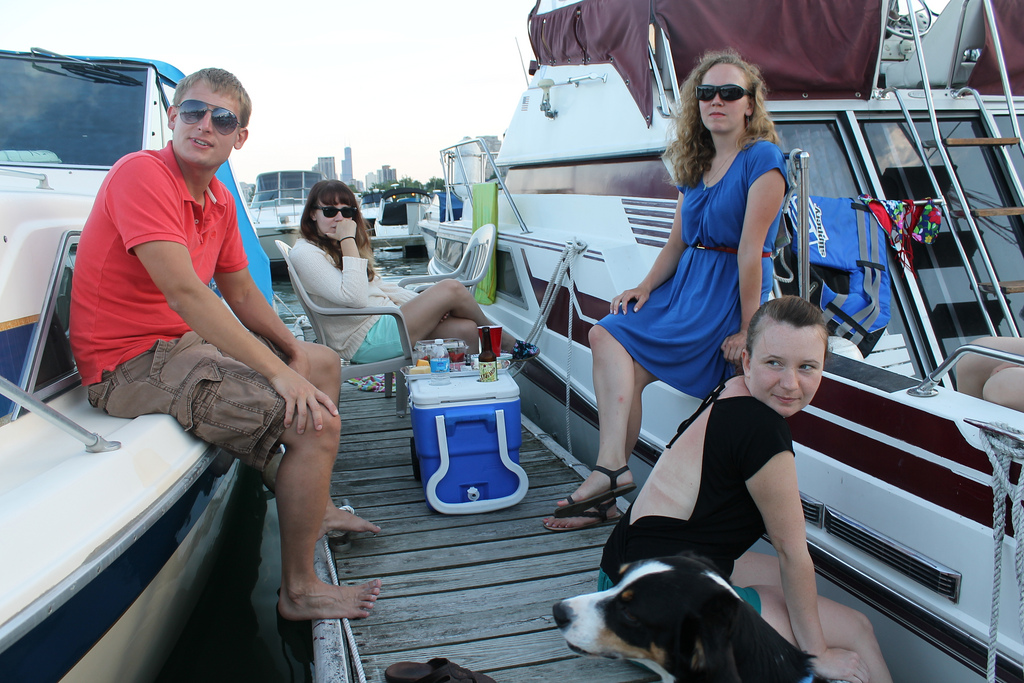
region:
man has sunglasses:
[155, 94, 248, 145]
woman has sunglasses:
[310, 200, 359, 224]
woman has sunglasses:
[692, 80, 754, 113]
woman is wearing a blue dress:
[597, 135, 788, 396]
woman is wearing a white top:
[294, 235, 387, 360]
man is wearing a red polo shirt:
[66, 134, 253, 375]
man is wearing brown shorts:
[63, 330, 289, 473]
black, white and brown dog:
[534, 554, 795, 679]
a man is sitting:
[71, 69, 385, 611]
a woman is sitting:
[596, 296, 895, 679]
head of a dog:
[554, 551, 793, 679]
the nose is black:
[552, 599, 572, 628]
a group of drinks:
[406, 322, 506, 386]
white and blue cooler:
[403, 368, 528, 514]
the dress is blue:
[601, 141, 786, 392]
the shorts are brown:
[90, 331, 284, 484]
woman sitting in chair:
[276, 179, 493, 407]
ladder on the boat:
[901, 94, 1022, 329]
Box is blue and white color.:
[405, 365, 536, 520]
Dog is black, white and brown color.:
[514, 554, 755, 681]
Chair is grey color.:
[266, 235, 419, 384]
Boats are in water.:
[0, 97, 314, 677]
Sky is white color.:
[265, 37, 465, 139]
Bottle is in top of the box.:
[411, 309, 513, 411]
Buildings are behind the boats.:
[305, 140, 410, 199]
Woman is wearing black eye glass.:
[632, 55, 787, 373]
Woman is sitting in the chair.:
[297, 172, 481, 454]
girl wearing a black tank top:
[592, 301, 890, 679]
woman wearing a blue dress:
[547, 54, 779, 535]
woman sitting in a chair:
[273, 173, 534, 363]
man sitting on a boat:
[2, 45, 383, 672]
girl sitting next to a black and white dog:
[547, 291, 901, 680]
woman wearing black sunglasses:
[659, 48, 778, 146]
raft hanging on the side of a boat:
[408, 135, 533, 333]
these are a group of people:
[119, 61, 945, 618]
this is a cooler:
[356, 317, 576, 542]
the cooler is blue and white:
[348, 368, 623, 653]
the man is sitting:
[62, 89, 376, 494]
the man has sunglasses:
[128, 83, 334, 150]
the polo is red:
[45, 142, 324, 395]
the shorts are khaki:
[61, 330, 347, 485]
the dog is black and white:
[529, 570, 805, 666]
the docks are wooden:
[368, 521, 569, 680]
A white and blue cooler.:
[398, 361, 535, 516]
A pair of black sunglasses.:
[697, 80, 751, 103]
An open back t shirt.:
[597, 383, 794, 580]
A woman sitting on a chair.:
[284, 178, 544, 360]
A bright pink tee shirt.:
[62, 143, 249, 387]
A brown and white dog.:
[548, 550, 839, 677]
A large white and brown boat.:
[382, 0, 1021, 677]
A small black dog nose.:
[546, 592, 572, 635]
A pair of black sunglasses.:
[176, 96, 243, 132]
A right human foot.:
[273, 575, 381, 623]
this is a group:
[81, 96, 843, 577]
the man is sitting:
[73, 124, 406, 577]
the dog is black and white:
[519, 592, 755, 653]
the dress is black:
[575, 269, 870, 565]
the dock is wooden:
[357, 529, 614, 656]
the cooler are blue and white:
[345, 329, 596, 500]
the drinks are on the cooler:
[381, 285, 585, 416]